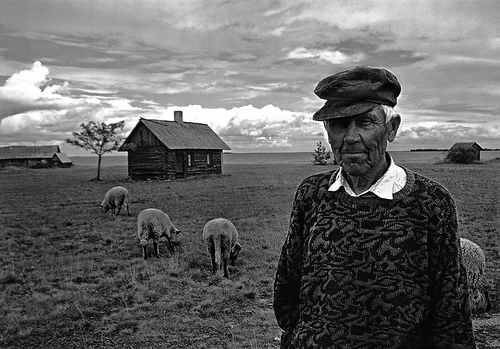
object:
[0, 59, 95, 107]
cloud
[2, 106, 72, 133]
cloud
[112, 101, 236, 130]
cloud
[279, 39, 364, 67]
cloud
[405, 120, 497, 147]
cloud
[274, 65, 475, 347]
man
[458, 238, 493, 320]
sheep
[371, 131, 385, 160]
wrinkles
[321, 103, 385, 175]
face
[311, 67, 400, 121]
cap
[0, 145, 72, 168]
building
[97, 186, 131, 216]
sheep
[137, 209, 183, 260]
sheep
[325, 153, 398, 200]
collar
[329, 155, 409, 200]
shirt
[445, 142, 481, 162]
hut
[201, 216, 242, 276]
animal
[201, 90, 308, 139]
cloud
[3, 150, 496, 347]
field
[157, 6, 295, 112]
cloud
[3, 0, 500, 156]
sky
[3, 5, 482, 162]
distance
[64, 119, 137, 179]
tree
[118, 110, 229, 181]
building